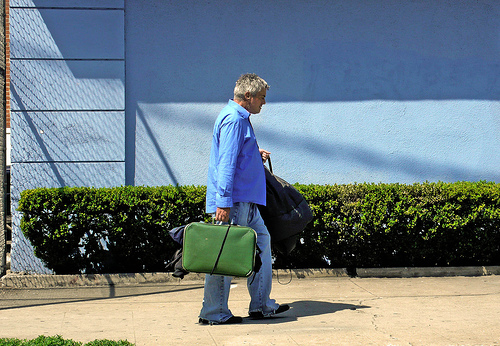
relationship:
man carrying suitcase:
[197, 65, 294, 325] [181, 218, 261, 287]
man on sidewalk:
[197, 65, 294, 325] [28, 290, 371, 331]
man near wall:
[197, 65, 294, 325] [272, 15, 476, 168]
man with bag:
[197, 65, 294, 325] [271, 176, 313, 230]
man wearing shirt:
[197, 65, 294, 325] [218, 114, 258, 185]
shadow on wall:
[160, 34, 187, 96] [272, 15, 476, 168]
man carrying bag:
[197, 65, 294, 325] [271, 176, 313, 230]